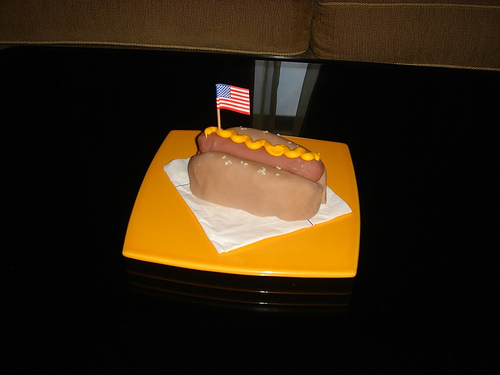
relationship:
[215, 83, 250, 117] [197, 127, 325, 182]
flag on top of hot dog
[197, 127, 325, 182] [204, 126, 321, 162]
hot dog has mustard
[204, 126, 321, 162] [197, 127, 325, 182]
mustard on top of hot dog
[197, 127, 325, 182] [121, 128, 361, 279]
hot dog served on plate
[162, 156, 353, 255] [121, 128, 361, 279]
napkin on top of plate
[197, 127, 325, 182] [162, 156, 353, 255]
hot dog served on napkin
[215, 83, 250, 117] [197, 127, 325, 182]
flag stuck inside hot dog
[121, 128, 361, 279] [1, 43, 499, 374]
plate sitting on surface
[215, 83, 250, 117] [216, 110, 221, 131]
flag attached to toothpick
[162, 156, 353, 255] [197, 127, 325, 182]
napkin underneath hot dog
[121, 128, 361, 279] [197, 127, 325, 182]
plate holding hot dog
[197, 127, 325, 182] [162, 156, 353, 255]
hot dog resting on napkin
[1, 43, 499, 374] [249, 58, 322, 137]
surface reflects window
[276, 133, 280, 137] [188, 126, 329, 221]
sesame seed decorating hot dog bun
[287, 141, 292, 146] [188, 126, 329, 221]
sesame seed decorating hot dog bun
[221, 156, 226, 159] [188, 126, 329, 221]
sesame seed decorating hot dog bun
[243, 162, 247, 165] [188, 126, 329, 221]
sesame seed decorating hot dog bun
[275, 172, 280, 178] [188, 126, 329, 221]
sesame seed decorating hot dog bun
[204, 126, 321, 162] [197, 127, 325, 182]
mustard decorating hot dog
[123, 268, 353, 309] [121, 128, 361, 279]
reflection made by plate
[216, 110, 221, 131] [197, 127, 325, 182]
toothpick stuck into hot dog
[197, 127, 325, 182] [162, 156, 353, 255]
hot dog sitting on napkin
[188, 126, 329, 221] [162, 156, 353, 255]
hot dog bun sitting on napkin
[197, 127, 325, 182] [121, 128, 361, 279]
hot dog on top of plate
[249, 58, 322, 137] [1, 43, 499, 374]
window reflected on surface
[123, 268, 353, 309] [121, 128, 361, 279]
reflection from plate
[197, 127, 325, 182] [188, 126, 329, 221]
hot dog inside of hot dog bun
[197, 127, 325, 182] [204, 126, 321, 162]
hot dog covered with mustard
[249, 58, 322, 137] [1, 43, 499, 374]
window reflecting on surface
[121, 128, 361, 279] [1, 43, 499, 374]
plate reflecting on surface